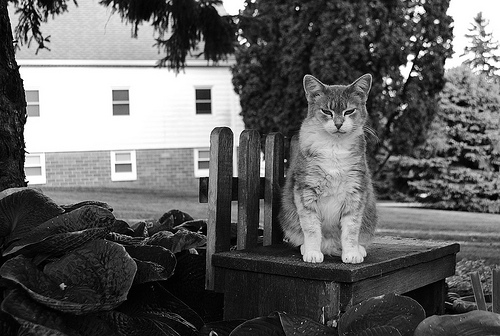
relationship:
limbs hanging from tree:
[158, 5, 260, 82] [0, 4, 257, 199]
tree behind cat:
[222, 2, 464, 174] [279, 77, 384, 272]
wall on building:
[24, 147, 199, 193] [6, 0, 267, 202]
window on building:
[111, 89, 130, 116] [6, 0, 267, 202]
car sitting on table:
[276, 72, 381, 263] [207, 237, 462, 331]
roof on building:
[2, 0, 251, 70] [5, 0, 265, 192]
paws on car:
[298, 245, 368, 265] [276, 72, 381, 263]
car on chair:
[276, 72, 381, 263] [195, 125, 460, 327]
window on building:
[23, 90, 41, 118] [28, 25, 242, 203]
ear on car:
[302, 73, 324, 95] [276, 72, 381, 263]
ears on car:
[299, 68, 375, 97] [276, 72, 381, 263]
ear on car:
[299, 70, 324, 95] [283, 67, 390, 269]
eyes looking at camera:
[325, 108, 357, 117] [1, 49, 457, 265]